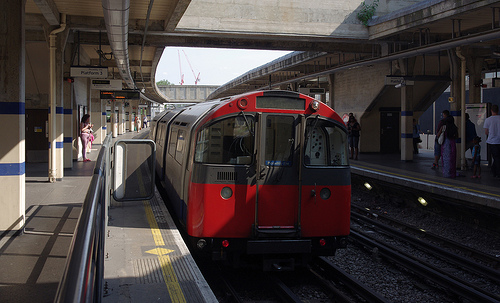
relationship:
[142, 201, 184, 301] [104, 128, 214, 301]
paint on a platform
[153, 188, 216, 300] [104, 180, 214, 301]
paint on a platform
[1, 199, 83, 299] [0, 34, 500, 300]
shadows on a train platform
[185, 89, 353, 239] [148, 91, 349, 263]
paint on a train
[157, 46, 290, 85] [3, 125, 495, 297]
sky above a platform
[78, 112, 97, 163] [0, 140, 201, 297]
lady on a platform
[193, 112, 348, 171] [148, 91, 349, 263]
windows on a train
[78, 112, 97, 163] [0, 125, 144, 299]
lady on a platform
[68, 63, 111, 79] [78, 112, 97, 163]
sign above a lady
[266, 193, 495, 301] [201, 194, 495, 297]
pebbles between tracks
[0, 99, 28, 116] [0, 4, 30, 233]
paint on pillar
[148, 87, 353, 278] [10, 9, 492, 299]
train at a station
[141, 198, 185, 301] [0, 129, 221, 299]
line at a train platform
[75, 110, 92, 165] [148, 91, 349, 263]
lady waiting for train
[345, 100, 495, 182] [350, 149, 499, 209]
people on a train platform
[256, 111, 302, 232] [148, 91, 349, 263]
door on a train